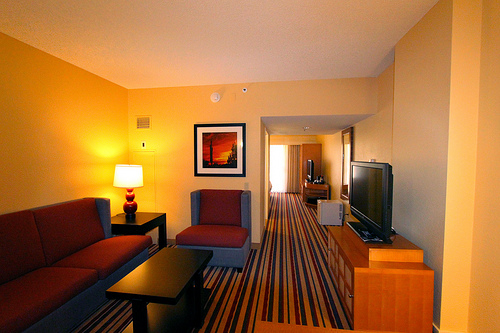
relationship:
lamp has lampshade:
[111, 164, 149, 218] [112, 163, 145, 191]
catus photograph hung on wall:
[191, 124, 245, 177] [127, 80, 383, 245]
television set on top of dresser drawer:
[346, 160, 394, 246] [324, 218, 436, 332]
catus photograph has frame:
[191, 124, 245, 177] [192, 121, 245, 179]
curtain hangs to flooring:
[288, 144, 303, 192] [40, 190, 434, 332]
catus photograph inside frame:
[191, 124, 245, 177] [192, 121, 245, 179]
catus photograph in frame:
[191, 124, 245, 177] [192, 121, 245, 179]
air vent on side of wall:
[138, 115, 150, 130] [127, 80, 383, 245]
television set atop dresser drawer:
[346, 160, 394, 246] [324, 218, 436, 332]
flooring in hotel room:
[40, 190, 434, 332] [3, 2, 500, 332]